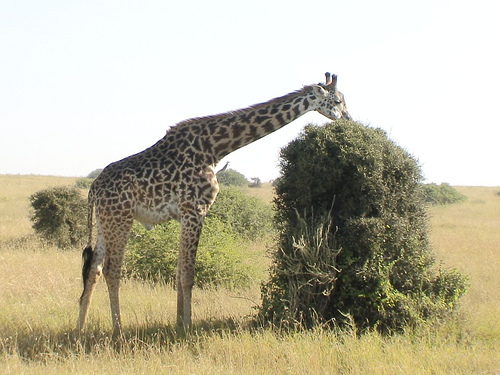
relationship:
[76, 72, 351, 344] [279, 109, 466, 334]
giraffe near a tree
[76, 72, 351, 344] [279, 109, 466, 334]
giraffe near tree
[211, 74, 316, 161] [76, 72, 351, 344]
neck of a giraffe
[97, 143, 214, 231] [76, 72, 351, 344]
body of a giraffe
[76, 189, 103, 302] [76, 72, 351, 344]
tail of a giraffe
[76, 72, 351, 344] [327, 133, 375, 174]
giraffe looking for food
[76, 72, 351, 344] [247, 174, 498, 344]
giraffe in a field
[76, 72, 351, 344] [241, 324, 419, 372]
giraffe standing in grass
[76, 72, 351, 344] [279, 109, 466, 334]
giraffe in bush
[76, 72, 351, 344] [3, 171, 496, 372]
giraffe in a field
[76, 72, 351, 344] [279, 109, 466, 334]
giraffe grazing a bush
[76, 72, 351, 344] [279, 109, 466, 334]
giraffe next to a bush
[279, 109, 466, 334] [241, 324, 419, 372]
bush in grass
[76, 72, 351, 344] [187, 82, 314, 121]
giraffe has a brown mane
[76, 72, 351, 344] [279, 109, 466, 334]
giraffe looking at a bush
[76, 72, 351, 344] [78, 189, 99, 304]
giraffe has a tail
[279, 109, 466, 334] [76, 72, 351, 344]
bush in front of giraffe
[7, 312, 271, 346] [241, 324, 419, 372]
shadow on grass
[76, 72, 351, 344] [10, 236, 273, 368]
giraffe in a grassland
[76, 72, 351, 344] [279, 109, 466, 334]
giraffe eating from a bush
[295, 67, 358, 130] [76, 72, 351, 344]
head of a giraffe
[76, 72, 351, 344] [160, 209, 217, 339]
giraffe has brown legs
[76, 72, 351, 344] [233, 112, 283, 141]
giraffe has spotted neck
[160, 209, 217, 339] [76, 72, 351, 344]
spotted legs of a giraffe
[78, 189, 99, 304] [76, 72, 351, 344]
tail of a giraffe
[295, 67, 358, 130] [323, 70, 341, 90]
head has horned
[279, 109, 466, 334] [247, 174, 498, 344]
bush in a field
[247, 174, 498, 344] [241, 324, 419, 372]
field full of grass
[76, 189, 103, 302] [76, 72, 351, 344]
tail on a giraffe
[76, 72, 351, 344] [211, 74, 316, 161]
giraffe has a long neck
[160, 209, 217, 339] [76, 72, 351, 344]
legs of a giraffe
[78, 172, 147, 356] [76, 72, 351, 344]
hind legs of a giraffe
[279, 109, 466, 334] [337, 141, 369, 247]
tree leafy green